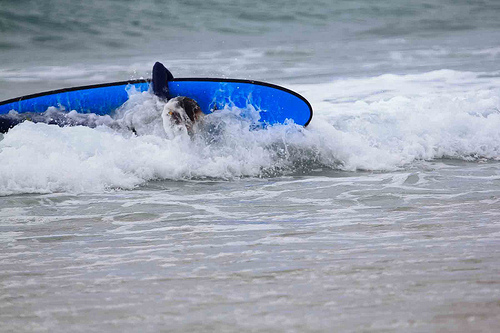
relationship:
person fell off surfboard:
[0, 61, 221, 147] [10, 71, 322, 151]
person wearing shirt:
[0, 61, 221, 147] [151, 62, 171, 107]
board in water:
[0, 77, 312, 134] [0, 2, 499, 332]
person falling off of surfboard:
[0, 61, 221, 147] [216, 77, 295, 134]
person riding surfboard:
[0, 61, 221, 147] [11, 60, 327, 155]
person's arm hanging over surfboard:
[146, 52, 177, 96] [214, 78, 271, 113]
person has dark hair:
[105, 57, 217, 149] [160, 95, 200, 131]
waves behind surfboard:
[1, 1, 398, 62] [0, 56, 320, 138]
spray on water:
[1, 70, 499, 197] [0, 2, 499, 332]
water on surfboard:
[0, 82, 314, 194] [0, 76, 314, 128]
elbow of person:
[150, 53, 171, 74] [138, 54, 210, 141]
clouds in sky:
[46, 3, 416, 58] [4, 1, 483, 27]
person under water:
[0, 61, 221, 147] [0, 2, 499, 332]